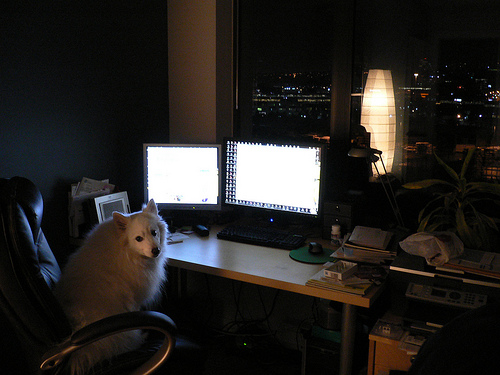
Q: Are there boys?
A: No, there are no boys.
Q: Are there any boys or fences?
A: No, there are no boys or fences.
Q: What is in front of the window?
A: The monitors are in front of the window.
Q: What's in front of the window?
A: The monitors are in front of the window.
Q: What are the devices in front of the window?
A: The devices are monitors.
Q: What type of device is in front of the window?
A: The devices are monitors.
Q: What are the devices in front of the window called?
A: The devices are monitors.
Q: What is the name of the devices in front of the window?
A: The devices are monitors.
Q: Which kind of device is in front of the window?
A: The devices are monitors.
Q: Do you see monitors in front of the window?
A: Yes, there are monitors in front of the window.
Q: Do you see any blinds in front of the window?
A: No, there are monitors in front of the window.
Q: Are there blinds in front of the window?
A: No, there are monitors in front of the window.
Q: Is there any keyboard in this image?
A: Yes, there is a keyboard.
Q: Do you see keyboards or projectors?
A: Yes, there is a keyboard.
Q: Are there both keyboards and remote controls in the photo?
A: No, there is a keyboard but no remote controls.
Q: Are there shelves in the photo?
A: No, there are no shelves.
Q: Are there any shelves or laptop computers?
A: No, there are no shelves or laptop computers.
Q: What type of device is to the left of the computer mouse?
A: The device is a keyboard.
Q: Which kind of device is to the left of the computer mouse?
A: The device is a keyboard.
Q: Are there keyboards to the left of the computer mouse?
A: Yes, there is a keyboard to the left of the computer mouse.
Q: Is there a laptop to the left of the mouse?
A: No, there is a keyboard to the left of the mouse.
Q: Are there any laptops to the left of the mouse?
A: No, there is a keyboard to the left of the mouse.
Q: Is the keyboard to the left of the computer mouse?
A: Yes, the keyboard is to the left of the computer mouse.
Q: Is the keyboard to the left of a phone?
A: No, the keyboard is to the left of the computer mouse.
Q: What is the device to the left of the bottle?
A: The device is a keyboard.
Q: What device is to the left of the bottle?
A: The device is a keyboard.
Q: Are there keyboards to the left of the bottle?
A: Yes, there is a keyboard to the left of the bottle.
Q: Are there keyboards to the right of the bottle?
A: No, the keyboard is to the left of the bottle.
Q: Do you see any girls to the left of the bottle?
A: No, there is a keyboard to the left of the bottle.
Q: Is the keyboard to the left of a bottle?
A: Yes, the keyboard is to the left of a bottle.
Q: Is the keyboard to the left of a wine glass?
A: No, the keyboard is to the left of a bottle.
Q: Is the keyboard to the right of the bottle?
A: No, the keyboard is to the left of the bottle.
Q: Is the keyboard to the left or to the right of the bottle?
A: The keyboard is to the left of the bottle.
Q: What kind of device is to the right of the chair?
A: The device is a keyboard.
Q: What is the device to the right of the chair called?
A: The device is a keyboard.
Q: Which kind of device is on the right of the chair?
A: The device is a keyboard.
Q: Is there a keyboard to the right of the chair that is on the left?
A: Yes, there is a keyboard to the right of the chair.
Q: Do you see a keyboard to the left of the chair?
A: No, the keyboard is to the right of the chair.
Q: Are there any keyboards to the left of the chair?
A: No, the keyboard is to the right of the chair.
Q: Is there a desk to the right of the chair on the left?
A: No, there is a keyboard to the right of the chair.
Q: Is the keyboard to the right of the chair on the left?
A: Yes, the keyboard is to the right of the chair.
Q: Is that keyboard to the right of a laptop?
A: No, the keyboard is to the right of the chair.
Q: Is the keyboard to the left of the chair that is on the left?
A: No, the keyboard is to the right of the chair.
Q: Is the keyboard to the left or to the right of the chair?
A: The keyboard is to the right of the chair.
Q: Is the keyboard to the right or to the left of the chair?
A: The keyboard is to the right of the chair.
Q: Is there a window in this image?
A: Yes, there is a window.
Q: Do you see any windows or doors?
A: Yes, there is a window.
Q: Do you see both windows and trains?
A: No, there is a window but no trains.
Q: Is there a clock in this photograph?
A: No, there are no clocks.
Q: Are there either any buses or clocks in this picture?
A: No, there are no clocks or buses.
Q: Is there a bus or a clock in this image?
A: No, there are no clocks or buses.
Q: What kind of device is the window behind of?
A: The window is behind the monitors.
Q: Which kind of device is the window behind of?
A: The window is behind the monitors.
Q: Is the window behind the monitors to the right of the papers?
A: Yes, the window is behind the monitors.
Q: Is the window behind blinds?
A: No, the window is behind the monitors.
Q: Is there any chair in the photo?
A: Yes, there is a chair.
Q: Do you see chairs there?
A: Yes, there is a chair.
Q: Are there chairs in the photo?
A: Yes, there is a chair.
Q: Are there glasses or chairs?
A: Yes, there is a chair.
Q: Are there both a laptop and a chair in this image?
A: No, there is a chair but no laptops.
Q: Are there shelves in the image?
A: No, there are no shelves.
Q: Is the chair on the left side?
A: Yes, the chair is on the left of the image.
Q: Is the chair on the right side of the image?
A: No, the chair is on the left of the image.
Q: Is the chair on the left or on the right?
A: The chair is on the left of the image.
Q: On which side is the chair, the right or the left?
A: The chair is on the left of the image.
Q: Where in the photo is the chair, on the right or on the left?
A: The chair is on the left of the image.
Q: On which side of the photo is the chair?
A: The chair is on the left of the image.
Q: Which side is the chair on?
A: The chair is on the left of the image.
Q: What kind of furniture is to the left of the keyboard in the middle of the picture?
A: The piece of furniture is a chair.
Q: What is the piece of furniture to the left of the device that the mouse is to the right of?
A: The piece of furniture is a chair.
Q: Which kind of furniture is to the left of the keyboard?
A: The piece of furniture is a chair.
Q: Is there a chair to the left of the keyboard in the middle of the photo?
A: Yes, there is a chair to the left of the keyboard.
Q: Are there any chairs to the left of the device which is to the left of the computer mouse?
A: Yes, there is a chair to the left of the keyboard.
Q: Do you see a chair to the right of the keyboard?
A: No, the chair is to the left of the keyboard.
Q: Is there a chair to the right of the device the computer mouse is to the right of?
A: No, the chair is to the left of the keyboard.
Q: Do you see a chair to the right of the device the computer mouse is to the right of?
A: No, the chair is to the left of the keyboard.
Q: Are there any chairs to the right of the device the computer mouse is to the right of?
A: No, the chair is to the left of the keyboard.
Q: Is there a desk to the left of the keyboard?
A: No, there is a chair to the left of the keyboard.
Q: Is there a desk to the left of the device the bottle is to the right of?
A: No, there is a chair to the left of the keyboard.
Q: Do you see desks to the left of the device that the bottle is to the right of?
A: No, there is a chair to the left of the keyboard.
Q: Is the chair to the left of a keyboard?
A: Yes, the chair is to the left of a keyboard.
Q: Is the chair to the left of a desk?
A: No, the chair is to the left of a keyboard.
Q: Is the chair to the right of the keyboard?
A: No, the chair is to the left of the keyboard.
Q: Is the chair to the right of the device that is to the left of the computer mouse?
A: No, the chair is to the left of the keyboard.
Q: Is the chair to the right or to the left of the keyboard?
A: The chair is to the left of the keyboard.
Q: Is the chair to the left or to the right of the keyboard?
A: The chair is to the left of the keyboard.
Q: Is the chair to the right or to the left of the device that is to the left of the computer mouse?
A: The chair is to the left of the keyboard.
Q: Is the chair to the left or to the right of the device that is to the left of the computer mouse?
A: The chair is to the left of the keyboard.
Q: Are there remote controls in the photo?
A: No, there are no remote controls.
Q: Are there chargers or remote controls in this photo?
A: No, there are no remote controls or chargers.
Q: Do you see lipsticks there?
A: No, there are no lipsticks.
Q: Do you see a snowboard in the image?
A: No, there are no snowboards.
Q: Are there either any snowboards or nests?
A: No, there are no snowboards or nests.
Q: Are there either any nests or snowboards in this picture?
A: No, there are no snowboards or nests.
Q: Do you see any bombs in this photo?
A: No, there are no bombs.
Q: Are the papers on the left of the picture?
A: Yes, the papers are on the left of the image.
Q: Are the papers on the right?
A: No, the papers are on the left of the image.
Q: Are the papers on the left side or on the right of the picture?
A: The papers are on the left of the image.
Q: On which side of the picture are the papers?
A: The papers are on the left of the image.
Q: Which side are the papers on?
A: The papers are on the left of the image.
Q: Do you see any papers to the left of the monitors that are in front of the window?
A: Yes, there are papers to the left of the monitors.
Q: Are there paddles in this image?
A: No, there are no paddles.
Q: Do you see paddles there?
A: No, there are no paddles.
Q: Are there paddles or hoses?
A: No, there are no paddles or hoses.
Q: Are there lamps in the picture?
A: Yes, there is a lamp.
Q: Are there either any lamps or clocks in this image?
A: Yes, there is a lamp.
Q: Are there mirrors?
A: No, there are no mirrors.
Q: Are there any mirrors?
A: No, there are no mirrors.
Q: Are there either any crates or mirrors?
A: No, there are no mirrors or crates.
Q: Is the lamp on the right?
A: Yes, the lamp is on the right of the image.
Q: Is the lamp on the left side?
A: No, the lamp is on the right of the image.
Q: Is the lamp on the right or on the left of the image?
A: The lamp is on the right of the image.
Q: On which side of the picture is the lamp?
A: The lamp is on the right of the image.